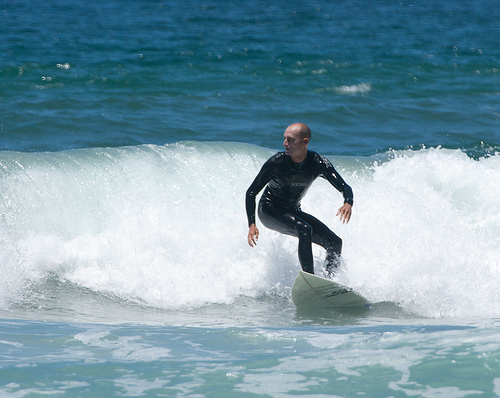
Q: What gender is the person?
A: Male.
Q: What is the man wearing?
A: Wetsuit.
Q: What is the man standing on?
A: Surfboard.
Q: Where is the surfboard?
A: Water.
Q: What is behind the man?
A: Wave.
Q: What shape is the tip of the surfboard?
A: Comes to a point.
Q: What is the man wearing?
A: A black wet suit.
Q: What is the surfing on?
A: A large foamy wave.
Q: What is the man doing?
A: Surfing.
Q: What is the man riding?
A: A surfboard.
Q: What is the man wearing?
A: A wetsuit.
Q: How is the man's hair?
A: Short and balding.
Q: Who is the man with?
A: Himself.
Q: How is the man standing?
A: Leaning and squatting.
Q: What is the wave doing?
A: Crashing.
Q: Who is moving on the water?
A: The surfer.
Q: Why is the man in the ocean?
A: To surf.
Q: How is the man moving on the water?
A: He is using a surfboard.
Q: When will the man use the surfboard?
A: When a wave comes.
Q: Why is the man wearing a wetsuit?
A: Because he is in the water.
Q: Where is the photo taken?
A: At the ocean.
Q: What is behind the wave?
A: Blue ocean.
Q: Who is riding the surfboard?
A: A man.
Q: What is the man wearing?
A: A wetsuit.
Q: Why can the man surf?
A: Because there are waves.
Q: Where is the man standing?
A: On the surfboard.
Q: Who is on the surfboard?
A: A surfer.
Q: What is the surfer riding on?
A: A surfboard.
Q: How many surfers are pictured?
A: One.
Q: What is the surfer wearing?
A: A wetsuit.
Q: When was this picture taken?
A: Daytime.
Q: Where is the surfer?
A: In the ocean.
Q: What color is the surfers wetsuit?
A: Black.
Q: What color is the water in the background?
A: Blue.